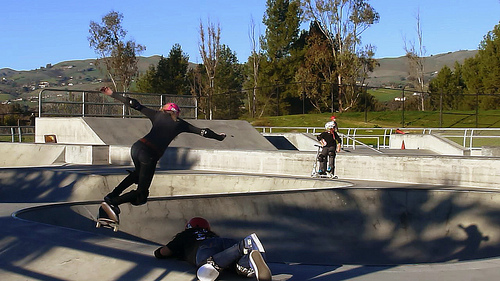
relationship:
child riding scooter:
[320, 122, 340, 173] [308, 145, 341, 178]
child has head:
[313, 120, 345, 174] [323, 117, 340, 137]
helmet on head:
[143, 97, 205, 124] [323, 117, 340, 137]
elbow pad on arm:
[123, 94, 138, 108] [111, 90, 158, 119]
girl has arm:
[99, 85, 226, 223] [111, 90, 158, 119]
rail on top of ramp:
[36, 83, 206, 119] [30, 113, 498, 164]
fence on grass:
[356, 82, 498, 126] [253, 101, 496, 145]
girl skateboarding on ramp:
[99, 85, 226, 223] [3, 186, 499, 280]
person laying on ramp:
[147, 203, 277, 267] [48, 202, 382, 279]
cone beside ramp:
[400, 136, 406, 151] [386, 123, 494, 159]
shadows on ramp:
[176, 167, 450, 279] [3, 186, 499, 280]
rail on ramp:
[36, 88, 213, 121] [42, 110, 280, 152]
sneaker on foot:
[103, 195, 120, 215] [102, 193, 120, 213]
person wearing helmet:
[154, 216, 274, 281] [183, 217, 213, 229]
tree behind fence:
[399, 5, 436, 117] [196, 77, 496, 134]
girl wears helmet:
[101, 85, 226, 209] [158, 100, 179, 111]